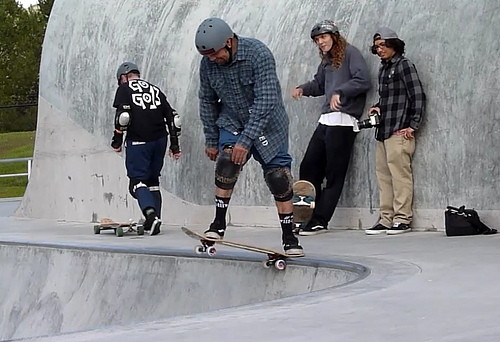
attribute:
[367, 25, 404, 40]
cap — gray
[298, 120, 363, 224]
pants — black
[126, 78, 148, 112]
letters — white, black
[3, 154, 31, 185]
fence — small, white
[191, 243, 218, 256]
wheels — white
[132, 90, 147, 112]
letters — white, black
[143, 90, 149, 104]
letters — black, white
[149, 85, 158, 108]
letters — black, white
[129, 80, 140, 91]
letters — black, white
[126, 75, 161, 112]
letter — black, white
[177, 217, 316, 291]
skateboard — large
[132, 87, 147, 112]
letter — black, white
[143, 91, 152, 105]
letter — black, white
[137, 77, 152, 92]
letter — black, white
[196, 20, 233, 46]
helmet — blue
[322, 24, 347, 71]
hair — long, curly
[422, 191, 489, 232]
bag — black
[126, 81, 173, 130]
letters — black, white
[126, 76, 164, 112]
letters — black, white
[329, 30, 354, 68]
hair — long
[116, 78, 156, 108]
words — white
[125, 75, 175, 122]
letters — black, white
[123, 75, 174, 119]
letters — white, black